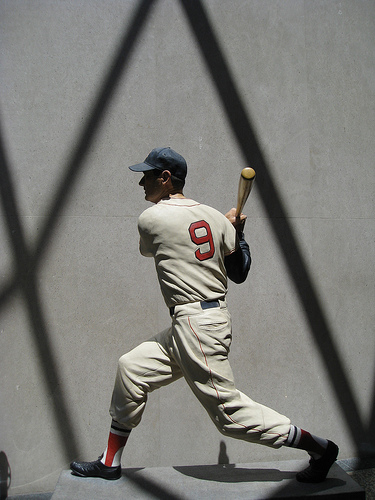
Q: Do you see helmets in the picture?
A: No, there are no helmets.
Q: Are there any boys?
A: No, there are no boys.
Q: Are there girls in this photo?
A: No, there are no girls.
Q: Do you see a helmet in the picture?
A: No, there are no helmets.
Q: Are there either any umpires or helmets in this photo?
A: No, there are no helmets or umpires.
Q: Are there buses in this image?
A: No, there are no buses.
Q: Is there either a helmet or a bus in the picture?
A: No, there are no buses or helmets.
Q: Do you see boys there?
A: No, there are no boys.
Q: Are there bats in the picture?
A: Yes, there is a bat.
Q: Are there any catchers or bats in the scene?
A: Yes, there is a bat.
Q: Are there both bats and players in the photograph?
A: Yes, there are both a bat and a player.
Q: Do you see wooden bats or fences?
A: Yes, there is a wood bat.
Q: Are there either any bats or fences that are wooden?
A: Yes, the bat is wooden.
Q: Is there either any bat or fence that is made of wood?
A: Yes, the bat is made of wood.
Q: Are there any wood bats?
A: Yes, there is a bat that is made of wood.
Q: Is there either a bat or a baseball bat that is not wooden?
A: No, there is a bat but it is wooden.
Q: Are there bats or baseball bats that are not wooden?
A: No, there is a bat but it is wooden.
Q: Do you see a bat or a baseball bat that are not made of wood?
A: No, there is a bat but it is made of wood.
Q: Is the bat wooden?
A: Yes, the bat is wooden.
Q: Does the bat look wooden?
A: Yes, the bat is wooden.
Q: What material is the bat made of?
A: The bat is made of wood.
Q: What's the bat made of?
A: The bat is made of wood.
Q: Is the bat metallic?
A: No, the bat is wooden.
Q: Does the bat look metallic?
A: No, the bat is wooden.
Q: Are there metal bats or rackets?
A: No, there is a bat but it is wooden.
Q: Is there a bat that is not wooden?
A: No, there is a bat but it is wooden.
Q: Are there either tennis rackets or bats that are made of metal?
A: No, there is a bat but it is made of wood.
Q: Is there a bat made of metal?
A: No, there is a bat but it is made of wood.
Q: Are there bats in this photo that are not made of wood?
A: No, there is a bat but it is made of wood.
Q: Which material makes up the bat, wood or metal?
A: The bat is made of wood.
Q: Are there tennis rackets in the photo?
A: No, there are no tennis rackets.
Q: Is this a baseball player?
A: Yes, this is a baseball player.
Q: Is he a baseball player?
A: Yes, this is a baseball player.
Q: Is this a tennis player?
A: No, this is a baseball player.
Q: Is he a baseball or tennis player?
A: This is a baseball player.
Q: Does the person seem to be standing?
A: Yes, the player is standing.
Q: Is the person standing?
A: Yes, the player is standing.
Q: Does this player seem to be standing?
A: Yes, the player is standing.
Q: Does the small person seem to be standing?
A: Yes, the player is standing.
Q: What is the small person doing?
A: The player is standing.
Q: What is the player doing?
A: The player is standing.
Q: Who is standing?
A: The player is standing.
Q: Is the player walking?
A: No, the player is standing.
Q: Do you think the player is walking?
A: No, the player is standing.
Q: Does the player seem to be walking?
A: No, the player is standing.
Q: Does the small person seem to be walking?
A: No, the player is standing.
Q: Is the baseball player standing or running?
A: The player is standing.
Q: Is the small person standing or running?
A: The player is standing.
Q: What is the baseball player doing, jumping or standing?
A: The player is standing.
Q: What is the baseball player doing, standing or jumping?
A: The player is standing.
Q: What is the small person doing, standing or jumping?
A: The player is standing.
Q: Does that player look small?
A: Yes, the player is small.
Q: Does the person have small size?
A: Yes, the player is small.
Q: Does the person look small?
A: Yes, the player is small.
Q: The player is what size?
A: The player is small.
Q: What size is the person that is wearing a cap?
A: The player is small.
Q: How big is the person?
A: The player is small.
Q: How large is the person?
A: The player is small.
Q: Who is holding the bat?
A: The player is holding the bat.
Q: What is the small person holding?
A: The player is holding the bat.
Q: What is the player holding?
A: The player is holding the bat.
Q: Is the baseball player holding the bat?
A: Yes, the player is holding the bat.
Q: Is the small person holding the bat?
A: Yes, the player is holding the bat.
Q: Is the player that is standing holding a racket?
A: No, the player is holding the bat.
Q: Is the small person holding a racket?
A: No, the player is holding the bat.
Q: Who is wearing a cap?
A: The player is wearing a cap.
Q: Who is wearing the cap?
A: The player is wearing a cap.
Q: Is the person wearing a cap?
A: Yes, the player is wearing a cap.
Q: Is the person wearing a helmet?
A: No, the player is wearing a cap.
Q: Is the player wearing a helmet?
A: No, the player is wearing a shoe.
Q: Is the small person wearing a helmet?
A: No, the player is wearing a shoe.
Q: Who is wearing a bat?
A: The player is wearing a bat.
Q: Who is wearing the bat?
A: The player is wearing a bat.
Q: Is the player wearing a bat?
A: Yes, the player is wearing a bat.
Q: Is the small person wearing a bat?
A: Yes, the player is wearing a bat.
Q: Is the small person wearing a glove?
A: No, the player is wearing a bat.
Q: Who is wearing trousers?
A: The player is wearing trousers.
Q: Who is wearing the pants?
A: The player is wearing trousers.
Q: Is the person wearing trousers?
A: Yes, the player is wearing trousers.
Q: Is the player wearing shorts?
A: No, the player is wearing trousers.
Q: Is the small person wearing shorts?
A: No, the player is wearing trousers.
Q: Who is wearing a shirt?
A: The player is wearing a shirt.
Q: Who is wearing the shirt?
A: The player is wearing a shirt.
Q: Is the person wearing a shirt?
A: Yes, the player is wearing a shirt.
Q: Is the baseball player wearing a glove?
A: No, the player is wearing a shirt.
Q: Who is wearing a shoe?
A: The player is wearing a shoe.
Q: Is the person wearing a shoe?
A: Yes, the player is wearing a shoe.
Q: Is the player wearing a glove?
A: No, the player is wearing a shoe.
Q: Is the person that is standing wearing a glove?
A: No, the player is wearing a shoe.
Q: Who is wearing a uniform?
A: The player is wearing a uniform.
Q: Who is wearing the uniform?
A: The player is wearing a uniform.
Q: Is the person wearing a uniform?
A: Yes, the player is wearing a uniform.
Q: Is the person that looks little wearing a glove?
A: No, the player is wearing a uniform.